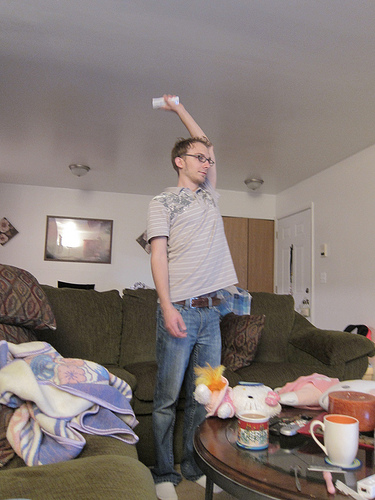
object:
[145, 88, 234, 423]
man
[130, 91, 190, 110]
gamecontroller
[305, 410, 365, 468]
mug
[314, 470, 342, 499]
candle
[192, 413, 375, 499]
table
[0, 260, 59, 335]
pillow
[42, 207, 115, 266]
picture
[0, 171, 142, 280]
wall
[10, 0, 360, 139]
ceiling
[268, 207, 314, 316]
door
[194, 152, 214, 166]
eyeglasses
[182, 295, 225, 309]
belt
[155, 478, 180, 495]
socks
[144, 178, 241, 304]
shirt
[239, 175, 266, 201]
lightfixtures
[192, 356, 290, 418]
kittydolls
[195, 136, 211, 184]
mansface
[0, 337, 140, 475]
blanket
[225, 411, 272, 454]
coffee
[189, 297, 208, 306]
beltbuckle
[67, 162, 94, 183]
light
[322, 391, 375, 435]
candle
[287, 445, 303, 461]
glasstop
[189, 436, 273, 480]
wood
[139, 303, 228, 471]
jeans